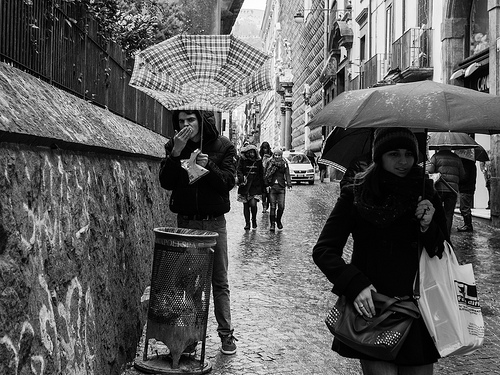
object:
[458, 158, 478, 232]
people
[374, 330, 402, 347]
pattern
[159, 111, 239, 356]
man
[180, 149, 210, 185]
food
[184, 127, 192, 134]
mouth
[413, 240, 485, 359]
bag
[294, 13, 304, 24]
lamp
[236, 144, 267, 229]
pedestrians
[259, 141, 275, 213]
pedestrians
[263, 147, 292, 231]
pedestrians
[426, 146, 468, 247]
pedestrians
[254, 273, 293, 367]
road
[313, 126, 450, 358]
person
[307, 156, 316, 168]
person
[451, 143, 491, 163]
umbrella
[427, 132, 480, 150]
umbrella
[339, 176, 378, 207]
shoulder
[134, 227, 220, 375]
waste bin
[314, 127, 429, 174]
umbrella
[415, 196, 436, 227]
hand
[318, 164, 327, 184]
people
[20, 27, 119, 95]
fence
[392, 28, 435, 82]
balcony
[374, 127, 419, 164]
hat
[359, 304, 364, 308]
ring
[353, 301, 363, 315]
finger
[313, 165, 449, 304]
shirt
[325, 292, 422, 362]
bag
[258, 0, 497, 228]
buildings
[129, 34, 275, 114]
plaid umbrella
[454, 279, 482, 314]
image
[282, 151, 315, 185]
car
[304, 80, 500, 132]
umbrella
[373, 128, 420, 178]
head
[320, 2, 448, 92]
wall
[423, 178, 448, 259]
arm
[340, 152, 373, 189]
person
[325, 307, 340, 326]
studs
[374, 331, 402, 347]
studs